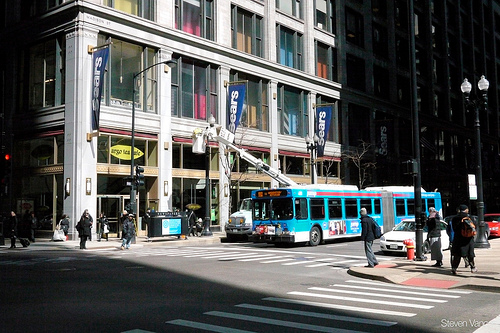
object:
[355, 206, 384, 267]
passenger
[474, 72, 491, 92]
light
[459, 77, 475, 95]
light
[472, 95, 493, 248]
pole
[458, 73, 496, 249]
street lamps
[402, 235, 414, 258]
fire hydrant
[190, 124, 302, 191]
ramp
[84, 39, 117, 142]
signs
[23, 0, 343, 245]
building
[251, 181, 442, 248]
blue bus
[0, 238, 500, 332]
road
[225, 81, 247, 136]
banners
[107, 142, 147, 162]
sign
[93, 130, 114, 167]
window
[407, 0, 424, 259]
pole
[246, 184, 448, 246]
bus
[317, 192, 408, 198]
red stripe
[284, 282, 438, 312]
white lines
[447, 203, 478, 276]
people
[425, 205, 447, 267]
people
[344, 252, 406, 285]
corner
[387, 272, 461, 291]
block painted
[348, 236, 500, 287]
sidewalk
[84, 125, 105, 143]
signal